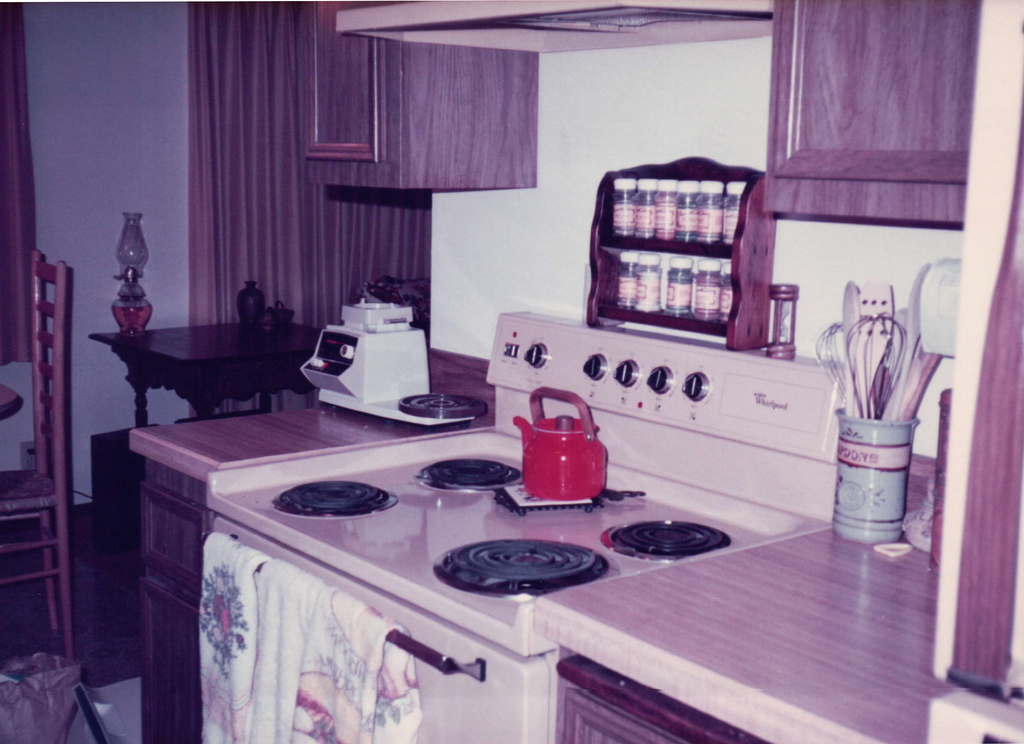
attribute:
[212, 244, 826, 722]
oven — white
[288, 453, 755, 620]
burners — black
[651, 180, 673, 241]
bottle —  of spices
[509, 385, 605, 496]
tea pot — red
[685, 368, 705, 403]
oven knof — black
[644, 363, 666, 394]
oven knob — black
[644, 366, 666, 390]
oven knob — black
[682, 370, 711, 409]
oven knob — black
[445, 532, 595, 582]
burner — black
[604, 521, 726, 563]
burner — black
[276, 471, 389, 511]
burner — black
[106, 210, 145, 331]
lamp — old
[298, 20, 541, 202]
cabinet — brown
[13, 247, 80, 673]
chair — wood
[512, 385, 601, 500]
kettle — red